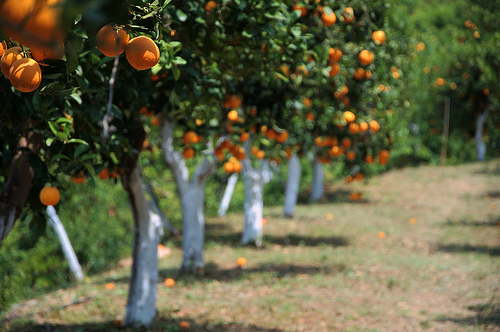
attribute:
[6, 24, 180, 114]
oranges — orange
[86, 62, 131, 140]
branches — tree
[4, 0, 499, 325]
line — orange trees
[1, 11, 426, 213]
oranges —  outside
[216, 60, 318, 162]
trees — orange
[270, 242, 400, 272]
grass — dead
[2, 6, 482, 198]
trees — orange